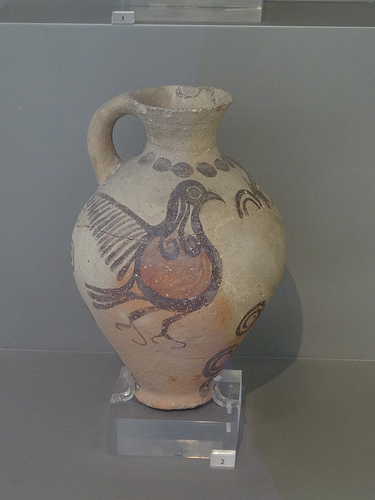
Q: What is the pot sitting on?
A: A clear glass base.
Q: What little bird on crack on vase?
A: Bird on light brown vase.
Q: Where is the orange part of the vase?
A: Middle of vase.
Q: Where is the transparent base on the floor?
A: Near clear object.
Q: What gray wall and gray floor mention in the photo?
A: Wall in the back of vase.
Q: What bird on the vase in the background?
A: The black and orange bird.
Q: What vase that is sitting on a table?
A: Vase on gray table.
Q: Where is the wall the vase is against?
A: Back of vase.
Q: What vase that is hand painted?
A: On the table.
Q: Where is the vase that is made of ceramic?
A: On the glass base.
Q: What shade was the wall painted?
A: Grey.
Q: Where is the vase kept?
A: The museum.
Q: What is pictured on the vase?
A: A bird.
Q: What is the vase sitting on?
A: Glass base.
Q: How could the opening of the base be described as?
A: Circular.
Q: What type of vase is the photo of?
A: Antique.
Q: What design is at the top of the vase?
A: Dots.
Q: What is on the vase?
A: A bird.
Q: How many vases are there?
A: One.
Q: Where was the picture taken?
A: At a museum.